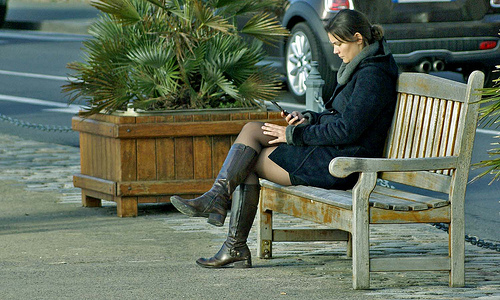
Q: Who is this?
A: Lady.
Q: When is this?
A: Daytime.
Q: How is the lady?
A: Seated.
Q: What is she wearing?
A: Boots.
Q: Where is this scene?
A: Outside in the city.